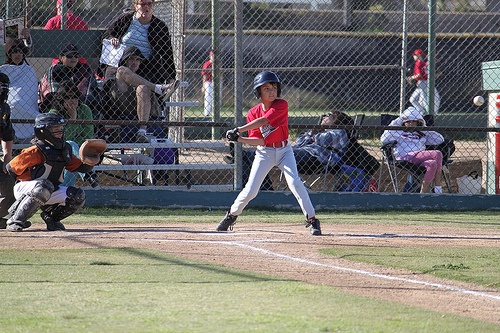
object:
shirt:
[242, 100, 287, 144]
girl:
[377, 105, 443, 196]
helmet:
[249, 69, 280, 91]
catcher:
[4, 115, 106, 233]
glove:
[75, 136, 105, 167]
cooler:
[140, 132, 166, 157]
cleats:
[218, 212, 235, 232]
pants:
[411, 152, 443, 182]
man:
[103, 0, 180, 145]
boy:
[209, 70, 324, 234]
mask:
[50, 121, 66, 145]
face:
[44, 117, 63, 136]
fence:
[0, 0, 499, 189]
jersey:
[240, 100, 288, 140]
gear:
[6, 195, 43, 232]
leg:
[110, 59, 158, 94]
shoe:
[217, 206, 237, 233]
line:
[230, 238, 499, 301]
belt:
[260, 137, 290, 151]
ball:
[473, 95, 484, 107]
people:
[44, 44, 93, 96]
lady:
[224, 112, 355, 192]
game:
[0, 5, 499, 330]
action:
[0, 83, 499, 332]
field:
[0, 204, 499, 332]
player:
[404, 49, 431, 116]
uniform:
[401, 60, 431, 112]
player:
[201, 53, 215, 114]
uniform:
[197, 61, 209, 115]